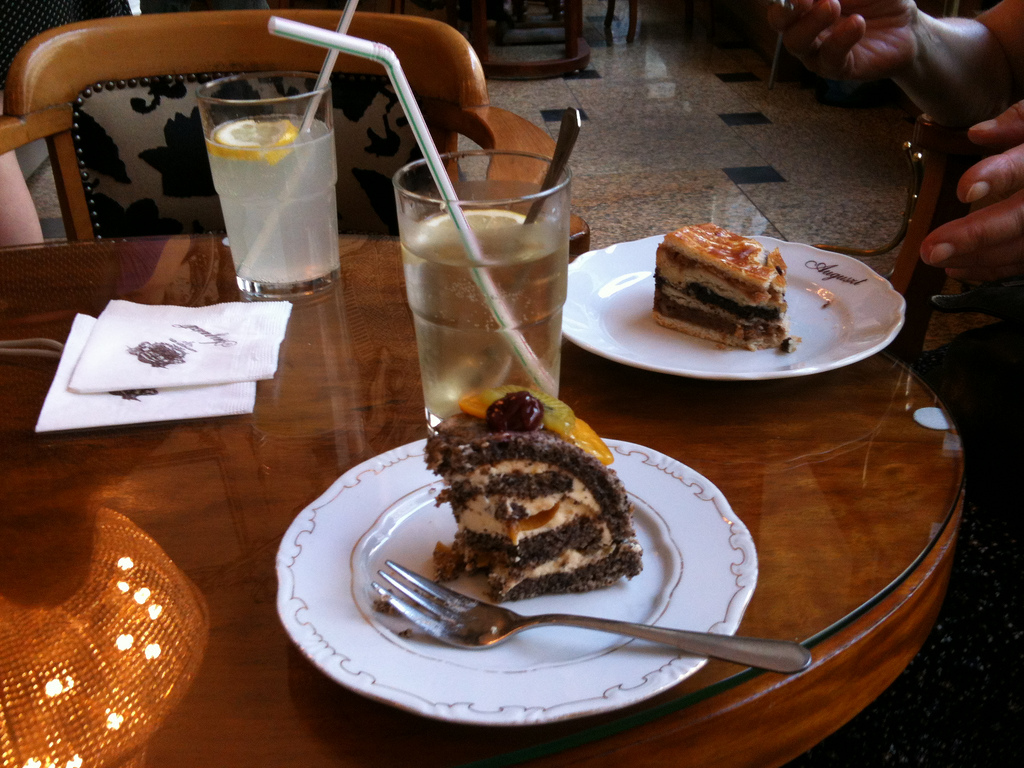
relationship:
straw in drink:
[256, 1, 580, 426] [379, 137, 585, 451]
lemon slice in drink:
[209, 107, 296, 166] [184, 11, 350, 302]